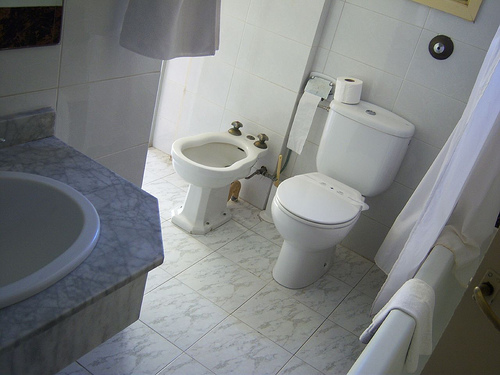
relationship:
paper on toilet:
[330, 77, 364, 105] [271, 97, 416, 289]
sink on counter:
[0, 167, 101, 307] [0, 129, 163, 349]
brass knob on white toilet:
[248, 119, 269, 179] [161, 135, 241, 171]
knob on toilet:
[228, 117, 245, 139] [168, 118, 273, 240]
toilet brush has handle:
[254, 152, 287, 229] [270, 151, 285, 183]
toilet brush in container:
[254, 152, 287, 229] [253, 183, 278, 228]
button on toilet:
[362, 104, 378, 119] [271, 97, 416, 289]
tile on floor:
[231, 283, 326, 357] [59, 146, 400, 373]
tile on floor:
[167, 249, 273, 318] [59, 146, 400, 373]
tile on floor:
[76, 322, 185, 372] [59, 146, 400, 373]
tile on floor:
[291, 314, 362, 373] [59, 146, 400, 373]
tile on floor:
[210, 225, 279, 288] [59, 146, 400, 373]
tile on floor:
[142, 179, 184, 227] [65, 160, 365, 372]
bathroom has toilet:
[1, 9, 491, 372] [271, 97, 416, 289]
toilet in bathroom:
[265, 101, 415, 292] [1, 9, 491, 372]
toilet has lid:
[271, 97, 416, 289] [272, 169, 363, 226]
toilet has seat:
[265, 101, 415, 292] [273, 192, 361, 229]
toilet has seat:
[271, 97, 416, 289] [270, 186, 360, 229]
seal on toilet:
[288, 157, 382, 238] [241, 90, 427, 318]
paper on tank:
[330, 75, 365, 105] [275, 91, 412, 191]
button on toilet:
[363, 107, 379, 117] [274, 98, 405, 289]